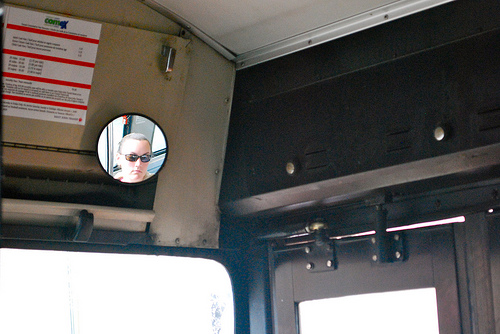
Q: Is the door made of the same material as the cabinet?
A: Yes, both the door and the cabinet are made of metal.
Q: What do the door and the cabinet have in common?
A: The material, both the door and the cabinet are metallic.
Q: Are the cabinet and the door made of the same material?
A: Yes, both the cabinet and the door are made of metal.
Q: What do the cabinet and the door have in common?
A: The material, both the cabinet and the door are metallic.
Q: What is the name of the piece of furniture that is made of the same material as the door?
A: The piece of furniture is a cabinet.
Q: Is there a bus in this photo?
A: Yes, there is a bus.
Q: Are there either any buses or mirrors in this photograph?
A: Yes, there is a bus.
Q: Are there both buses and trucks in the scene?
A: No, there is a bus but no trucks.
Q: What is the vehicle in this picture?
A: The vehicle is a bus.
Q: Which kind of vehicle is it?
A: The vehicle is a bus.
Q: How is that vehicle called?
A: This is a bus.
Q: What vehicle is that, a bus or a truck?
A: This is a bus.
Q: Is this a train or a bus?
A: This is a bus.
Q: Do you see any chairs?
A: No, there are no chairs.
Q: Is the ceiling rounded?
A: Yes, the ceiling is rounded.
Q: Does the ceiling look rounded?
A: Yes, the ceiling is rounded.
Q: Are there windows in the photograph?
A: Yes, there is a window.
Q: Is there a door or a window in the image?
A: Yes, there is a window.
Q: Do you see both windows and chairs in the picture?
A: No, there is a window but no chairs.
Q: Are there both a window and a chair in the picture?
A: No, there is a window but no chairs.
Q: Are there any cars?
A: No, there are no cars.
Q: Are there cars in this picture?
A: No, there are no cars.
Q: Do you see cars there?
A: No, there are no cars.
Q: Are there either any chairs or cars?
A: No, there are no cars or chairs.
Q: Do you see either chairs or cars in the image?
A: No, there are no cars or chairs.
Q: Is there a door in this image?
A: Yes, there is a door.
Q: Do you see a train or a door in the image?
A: Yes, there is a door.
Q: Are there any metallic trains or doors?
A: Yes, there is a metal door.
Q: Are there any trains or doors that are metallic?
A: Yes, the door is metallic.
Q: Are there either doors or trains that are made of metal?
A: Yes, the door is made of metal.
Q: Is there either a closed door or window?
A: Yes, there is a closed door.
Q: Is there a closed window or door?
A: Yes, there is a closed door.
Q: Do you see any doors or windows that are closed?
A: Yes, the door is closed.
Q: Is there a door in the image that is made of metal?
A: Yes, there is a door that is made of metal.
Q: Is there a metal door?
A: Yes, there is a door that is made of metal.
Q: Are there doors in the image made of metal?
A: Yes, there is a door that is made of metal.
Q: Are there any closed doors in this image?
A: Yes, there is a closed door.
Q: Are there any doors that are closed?
A: Yes, there is a door that is closed.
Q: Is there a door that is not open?
A: Yes, there is an closed door.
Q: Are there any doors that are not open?
A: Yes, there is an closed door.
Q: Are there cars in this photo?
A: No, there are no cars.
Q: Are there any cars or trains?
A: No, there are no cars or trains.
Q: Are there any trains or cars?
A: No, there are no cars or trains.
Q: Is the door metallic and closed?
A: Yes, the door is metallic and closed.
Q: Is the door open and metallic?
A: No, the door is metallic but closed.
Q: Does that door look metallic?
A: Yes, the door is metallic.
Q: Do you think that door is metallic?
A: Yes, the door is metallic.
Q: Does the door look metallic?
A: Yes, the door is metallic.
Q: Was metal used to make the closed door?
A: Yes, the door is made of metal.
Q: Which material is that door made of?
A: The door is made of metal.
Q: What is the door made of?
A: The door is made of metal.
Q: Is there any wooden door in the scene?
A: No, there is a door but it is metallic.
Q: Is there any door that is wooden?
A: No, there is a door but it is metallic.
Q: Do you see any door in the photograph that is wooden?
A: No, there is a door but it is metallic.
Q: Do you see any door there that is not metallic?
A: No, there is a door but it is metallic.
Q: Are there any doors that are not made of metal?
A: No, there is a door but it is made of metal.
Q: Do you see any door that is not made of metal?
A: No, there is a door but it is made of metal.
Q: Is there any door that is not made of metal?
A: No, there is a door but it is made of metal.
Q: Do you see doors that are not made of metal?
A: No, there is a door but it is made of metal.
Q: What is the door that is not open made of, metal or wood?
A: The door is made of metal.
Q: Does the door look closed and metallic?
A: Yes, the door is closed and metallic.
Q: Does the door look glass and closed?
A: No, the door is closed but metallic.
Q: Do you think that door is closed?
A: Yes, the door is closed.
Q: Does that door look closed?
A: Yes, the door is closed.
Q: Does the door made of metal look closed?
A: Yes, the door is closed.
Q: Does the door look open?
A: No, the door is closed.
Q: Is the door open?
A: No, the door is closed.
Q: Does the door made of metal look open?
A: No, the door is closed.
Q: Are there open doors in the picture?
A: No, there is a door but it is closed.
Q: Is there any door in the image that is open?
A: No, there is a door but it is closed.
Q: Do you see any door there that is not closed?
A: No, there is a door but it is closed.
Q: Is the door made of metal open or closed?
A: The door is closed.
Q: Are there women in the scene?
A: Yes, there is a woman.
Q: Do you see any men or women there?
A: Yes, there is a woman.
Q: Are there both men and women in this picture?
A: No, there is a woman but no men.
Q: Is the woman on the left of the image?
A: Yes, the woman is on the left of the image.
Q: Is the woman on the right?
A: No, the woman is on the left of the image.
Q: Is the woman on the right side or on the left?
A: The woman is on the left of the image.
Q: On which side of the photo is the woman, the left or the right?
A: The woman is on the left of the image.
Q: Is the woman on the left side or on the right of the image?
A: The woman is on the left of the image.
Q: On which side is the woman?
A: The woman is on the left of the image.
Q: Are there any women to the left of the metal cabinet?
A: Yes, there is a woman to the left of the cabinet.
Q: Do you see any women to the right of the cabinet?
A: No, the woman is to the left of the cabinet.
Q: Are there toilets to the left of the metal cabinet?
A: No, there is a woman to the left of the cabinet.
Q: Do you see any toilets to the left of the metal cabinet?
A: No, there is a woman to the left of the cabinet.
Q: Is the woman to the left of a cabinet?
A: Yes, the woman is to the left of a cabinet.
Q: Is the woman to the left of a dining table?
A: No, the woman is to the left of a cabinet.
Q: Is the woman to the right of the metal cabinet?
A: No, the woman is to the left of the cabinet.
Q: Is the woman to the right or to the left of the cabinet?
A: The woman is to the left of the cabinet.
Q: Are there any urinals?
A: No, there are no urinals.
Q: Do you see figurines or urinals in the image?
A: No, there are no urinals or figurines.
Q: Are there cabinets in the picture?
A: Yes, there is a cabinet.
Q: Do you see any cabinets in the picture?
A: Yes, there is a cabinet.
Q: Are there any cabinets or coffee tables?
A: Yes, there is a cabinet.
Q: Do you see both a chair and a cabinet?
A: No, there is a cabinet but no chairs.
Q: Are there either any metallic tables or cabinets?
A: Yes, there is a metal cabinet.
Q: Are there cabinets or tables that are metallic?
A: Yes, the cabinet is metallic.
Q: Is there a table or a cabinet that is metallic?
A: Yes, the cabinet is metallic.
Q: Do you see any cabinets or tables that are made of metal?
A: Yes, the cabinet is made of metal.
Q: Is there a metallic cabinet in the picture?
A: Yes, there is a metal cabinet.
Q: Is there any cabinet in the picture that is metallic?
A: Yes, there is a cabinet that is metallic.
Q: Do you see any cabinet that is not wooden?
A: Yes, there is a metallic cabinet.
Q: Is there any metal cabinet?
A: Yes, there is a cabinet that is made of metal.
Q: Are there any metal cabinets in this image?
A: Yes, there is a cabinet that is made of metal.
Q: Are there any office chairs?
A: No, there are no office chairs.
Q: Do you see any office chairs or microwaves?
A: No, there are no office chairs or microwaves.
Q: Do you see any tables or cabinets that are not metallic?
A: No, there is a cabinet but it is metallic.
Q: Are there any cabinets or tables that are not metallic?
A: No, there is a cabinet but it is metallic.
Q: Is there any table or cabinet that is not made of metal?
A: No, there is a cabinet but it is made of metal.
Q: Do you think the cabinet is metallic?
A: Yes, the cabinet is metallic.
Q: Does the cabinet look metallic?
A: Yes, the cabinet is metallic.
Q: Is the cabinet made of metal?
A: Yes, the cabinet is made of metal.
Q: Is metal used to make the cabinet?
A: Yes, the cabinet is made of metal.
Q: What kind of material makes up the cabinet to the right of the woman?
A: The cabinet is made of metal.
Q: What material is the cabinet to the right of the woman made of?
A: The cabinet is made of metal.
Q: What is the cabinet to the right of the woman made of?
A: The cabinet is made of metal.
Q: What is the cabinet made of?
A: The cabinet is made of metal.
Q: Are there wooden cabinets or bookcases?
A: No, there is a cabinet but it is metallic.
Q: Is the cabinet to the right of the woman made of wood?
A: No, the cabinet is made of metal.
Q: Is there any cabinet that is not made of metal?
A: No, there is a cabinet but it is made of metal.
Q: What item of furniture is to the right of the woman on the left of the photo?
A: The piece of furniture is a cabinet.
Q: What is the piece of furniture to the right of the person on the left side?
A: The piece of furniture is a cabinet.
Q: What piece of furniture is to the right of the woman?
A: The piece of furniture is a cabinet.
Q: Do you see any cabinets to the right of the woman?
A: Yes, there is a cabinet to the right of the woman.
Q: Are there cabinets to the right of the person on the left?
A: Yes, there is a cabinet to the right of the woman.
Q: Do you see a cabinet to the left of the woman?
A: No, the cabinet is to the right of the woman.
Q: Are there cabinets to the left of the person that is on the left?
A: No, the cabinet is to the right of the woman.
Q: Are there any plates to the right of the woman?
A: No, there is a cabinet to the right of the woman.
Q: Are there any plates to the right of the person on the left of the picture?
A: No, there is a cabinet to the right of the woman.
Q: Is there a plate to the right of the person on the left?
A: No, there is a cabinet to the right of the woman.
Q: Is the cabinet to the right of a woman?
A: Yes, the cabinet is to the right of a woman.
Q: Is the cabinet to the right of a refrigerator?
A: No, the cabinet is to the right of a woman.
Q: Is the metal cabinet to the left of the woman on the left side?
A: No, the cabinet is to the right of the woman.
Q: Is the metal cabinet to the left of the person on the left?
A: No, the cabinet is to the right of the woman.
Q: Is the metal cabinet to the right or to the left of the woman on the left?
A: The cabinet is to the right of the woman.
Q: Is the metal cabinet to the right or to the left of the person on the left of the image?
A: The cabinet is to the right of the woman.